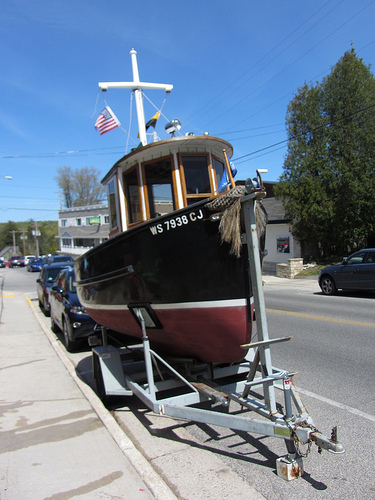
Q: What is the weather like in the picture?
A: It is sunny.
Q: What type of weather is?
A: It is sunny.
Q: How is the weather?
A: It is sunny.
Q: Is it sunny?
A: Yes, it is sunny.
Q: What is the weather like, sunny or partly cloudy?
A: It is sunny.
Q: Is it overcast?
A: No, it is sunny.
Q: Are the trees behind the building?
A: Yes, the trees are behind the building.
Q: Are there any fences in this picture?
A: No, there are no fences.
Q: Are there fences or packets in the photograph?
A: No, there are no fences or packets.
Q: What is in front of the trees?
A: The building is in front of the trees.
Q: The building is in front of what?
A: The building is in front of the trees.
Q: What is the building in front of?
A: The building is in front of the trees.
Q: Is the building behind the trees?
A: No, the building is in front of the trees.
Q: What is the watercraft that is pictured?
A: The watercraft is a ship.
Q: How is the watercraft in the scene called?
A: The watercraft is a ship.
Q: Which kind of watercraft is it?
A: The watercraft is a ship.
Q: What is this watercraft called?
A: That is a ship.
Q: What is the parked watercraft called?
A: The watercraft is a ship.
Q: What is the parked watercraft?
A: The watercraft is a ship.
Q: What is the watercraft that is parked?
A: The watercraft is a ship.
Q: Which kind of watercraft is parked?
A: The watercraft is a ship.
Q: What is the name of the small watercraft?
A: The watercraft is a ship.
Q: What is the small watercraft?
A: The watercraft is a ship.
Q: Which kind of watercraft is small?
A: The watercraft is a ship.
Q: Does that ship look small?
A: Yes, the ship is small.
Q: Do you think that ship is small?
A: Yes, the ship is small.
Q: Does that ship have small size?
A: Yes, the ship is small.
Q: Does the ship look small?
A: Yes, the ship is small.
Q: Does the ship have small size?
A: Yes, the ship is small.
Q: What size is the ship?
A: The ship is small.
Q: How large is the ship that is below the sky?
A: The ship is small.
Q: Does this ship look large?
A: No, the ship is small.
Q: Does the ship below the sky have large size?
A: No, the ship is small.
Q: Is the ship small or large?
A: The ship is small.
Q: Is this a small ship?
A: Yes, this is a small ship.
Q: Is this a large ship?
A: No, this is a small ship.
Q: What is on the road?
A: The ship is on the road.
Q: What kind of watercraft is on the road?
A: The watercraft is a ship.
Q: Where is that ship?
A: The ship is on the road.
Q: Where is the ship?
A: The ship is on the road.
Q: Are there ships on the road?
A: Yes, there is a ship on the road.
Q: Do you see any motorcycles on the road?
A: No, there is a ship on the road.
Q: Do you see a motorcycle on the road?
A: No, there is a ship on the road.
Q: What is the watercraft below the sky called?
A: The watercraft is a ship.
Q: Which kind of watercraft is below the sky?
A: The watercraft is a ship.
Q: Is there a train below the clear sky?
A: No, there is a ship below the sky.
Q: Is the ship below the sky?
A: Yes, the ship is below the sky.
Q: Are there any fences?
A: No, there are no fences.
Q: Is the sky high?
A: Yes, the sky is high.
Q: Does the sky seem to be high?
A: Yes, the sky is high.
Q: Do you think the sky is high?
A: Yes, the sky is high.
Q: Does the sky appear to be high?
A: Yes, the sky is high.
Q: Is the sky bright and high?
A: Yes, the sky is bright and high.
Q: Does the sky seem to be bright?
A: Yes, the sky is bright.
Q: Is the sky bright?
A: Yes, the sky is bright.